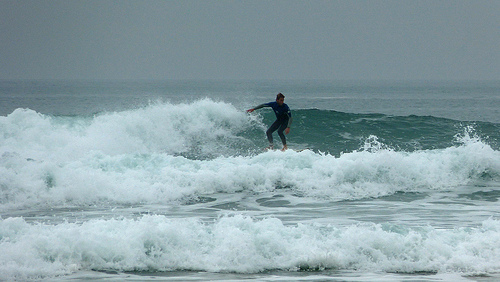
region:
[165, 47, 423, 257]
the man is surfing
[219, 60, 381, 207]
the man is surfing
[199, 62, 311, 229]
the man is surfing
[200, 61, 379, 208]
the man is surfing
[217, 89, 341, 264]
the man is surfing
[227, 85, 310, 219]
the man is surfing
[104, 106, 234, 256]
The waves are visible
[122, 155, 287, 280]
The waves are visible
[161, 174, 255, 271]
The waves are visible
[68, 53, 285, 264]
The waves are visible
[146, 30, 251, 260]
The waves are visible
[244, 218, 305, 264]
The waves are visible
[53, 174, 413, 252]
crashing waves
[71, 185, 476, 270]
the whitecaps of crashing waves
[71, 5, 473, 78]
gray sky in the background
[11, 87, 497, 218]
rough waves in the sea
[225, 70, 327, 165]
a man surfing on the rough waves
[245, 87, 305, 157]
the man's black wetsuit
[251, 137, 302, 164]
the man's bare feet standing on surfboard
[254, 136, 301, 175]
the man's hidden surfboard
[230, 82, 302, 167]
man is balancing on the surfboard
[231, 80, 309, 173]
the man is looking toward the crashing waves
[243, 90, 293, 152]
A man surfing in the water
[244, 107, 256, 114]
A man's right hand.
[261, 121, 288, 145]
Legs on a man surfing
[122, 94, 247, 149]
Large white wave to the left of a man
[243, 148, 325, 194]
Large white wave in front of a man.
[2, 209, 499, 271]
Large white wave furthest from a man surfing.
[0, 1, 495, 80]
Hazy blue and gray sky.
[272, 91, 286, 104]
Head of a man surfing.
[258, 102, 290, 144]
Black wetsuit on a man surfing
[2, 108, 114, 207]
Largest white wave in the water